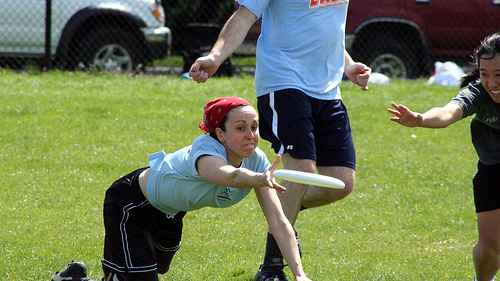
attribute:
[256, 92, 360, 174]
athletic shorts — black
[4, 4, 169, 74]
truck — white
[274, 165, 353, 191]
frisbee — white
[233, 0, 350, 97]
shirt — blue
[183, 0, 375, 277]
player — ultimate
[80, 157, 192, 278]
shorts — black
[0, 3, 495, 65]
fencing — metal 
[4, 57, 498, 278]
grass — green